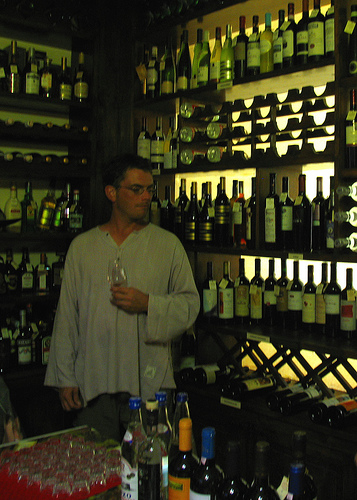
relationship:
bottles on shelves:
[230, 145, 345, 238] [196, 7, 329, 295]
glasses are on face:
[120, 182, 156, 193] [118, 169, 156, 216]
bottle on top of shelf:
[312, 176, 327, 256] [181, 239, 356, 262]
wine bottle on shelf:
[293, 173, 312, 251] [182, 241, 355, 260]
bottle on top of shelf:
[214, 256, 236, 324] [196, 316, 356, 359]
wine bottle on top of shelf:
[213, 173, 230, 246] [181, 239, 356, 262]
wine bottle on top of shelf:
[245, 176, 253, 245] [181, 239, 356, 262]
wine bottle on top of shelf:
[263, 170, 281, 247] [181, 239, 356, 262]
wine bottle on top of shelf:
[310, 177, 321, 246] [181, 239, 356, 262]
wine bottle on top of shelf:
[262, 258, 276, 325] [181, 239, 356, 262]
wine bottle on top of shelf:
[287, 260, 303, 328] [181, 239, 356, 262]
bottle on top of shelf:
[200, 179, 216, 247] [181, 239, 356, 262]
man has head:
[43, 150, 200, 439] [93, 151, 162, 223]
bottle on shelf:
[312, 176, 327, 256] [0, 22, 347, 436]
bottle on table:
[114, 385, 315, 498] [7, 440, 331, 497]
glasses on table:
[35, 442, 90, 486] [2, 422, 323, 497]